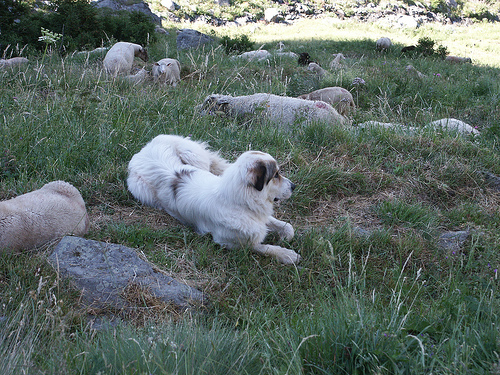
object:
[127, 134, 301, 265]
dog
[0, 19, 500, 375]
grass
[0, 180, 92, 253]
sheep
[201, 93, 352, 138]
sheep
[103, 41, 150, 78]
sheep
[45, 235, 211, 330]
rock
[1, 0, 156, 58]
bushes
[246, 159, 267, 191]
ears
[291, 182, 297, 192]
nose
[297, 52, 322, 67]
sheep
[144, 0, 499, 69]
ray of sun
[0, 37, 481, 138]
group of sheep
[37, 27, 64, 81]
plant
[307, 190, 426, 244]
patch of grass